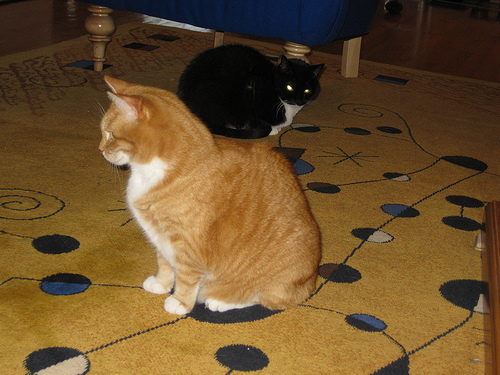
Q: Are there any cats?
A: Yes, there is a cat.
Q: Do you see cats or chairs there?
A: Yes, there is a cat.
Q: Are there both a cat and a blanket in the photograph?
A: No, there is a cat but no blankets.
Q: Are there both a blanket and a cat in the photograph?
A: No, there is a cat but no blankets.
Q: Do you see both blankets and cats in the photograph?
A: No, there is a cat but no blankets.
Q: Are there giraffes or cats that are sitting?
A: Yes, the cat is sitting.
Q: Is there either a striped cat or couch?
A: Yes, there is a striped cat.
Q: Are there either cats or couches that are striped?
A: Yes, the cat is striped.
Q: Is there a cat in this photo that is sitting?
A: Yes, there is a cat that is sitting.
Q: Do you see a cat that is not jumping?
A: Yes, there is a cat that is sitting .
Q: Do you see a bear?
A: No, there are no bears.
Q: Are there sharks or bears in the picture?
A: No, there are no bears or sharks.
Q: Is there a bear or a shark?
A: No, there are no bears or sharks.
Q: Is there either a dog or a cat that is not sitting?
A: No, there is a cat but it is sitting.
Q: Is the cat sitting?
A: Yes, the cat is sitting.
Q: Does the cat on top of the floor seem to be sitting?
A: Yes, the cat is sitting.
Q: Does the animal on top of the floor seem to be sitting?
A: Yes, the cat is sitting.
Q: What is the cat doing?
A: The cat is sitting.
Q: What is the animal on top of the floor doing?
A: The cat is sitting.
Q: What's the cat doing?
A: The cat is sitting.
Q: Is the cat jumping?
A: No, the cat is sitting.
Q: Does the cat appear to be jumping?
A: No, the cat is sitting.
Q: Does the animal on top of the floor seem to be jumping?
A: No, the cat is sitting.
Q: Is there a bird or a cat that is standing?
A: No, there is a cat but it is sitting.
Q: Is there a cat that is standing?
A: No, there is a cat but it is sitting.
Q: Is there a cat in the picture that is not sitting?
A: No, there is a cat but it is sitting.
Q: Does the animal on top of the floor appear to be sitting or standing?
A: The cat is sitting.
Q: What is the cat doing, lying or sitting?
A: The cat is sitting.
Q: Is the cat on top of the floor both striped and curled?
A: Yes, the cat is striped and curled.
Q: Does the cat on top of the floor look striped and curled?
A: Yes, the cat is striped and curled.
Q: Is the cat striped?
A: Yes, the cat is striped.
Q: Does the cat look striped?
A: Yes, the cat is striped.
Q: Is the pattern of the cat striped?
A: Yes, the cat is striped.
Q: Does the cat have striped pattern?
A: Yes, the cat is striped.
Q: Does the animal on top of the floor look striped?
A: Yes, the cat is striped.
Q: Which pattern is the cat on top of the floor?
A: The cat is striped.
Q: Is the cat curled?
A: Yes, the cat is curled.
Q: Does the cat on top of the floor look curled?
A: Yes, the cat is curled.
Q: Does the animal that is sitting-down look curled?
A: Yes, the cat is curled.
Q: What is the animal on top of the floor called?
A: The animal is a cat.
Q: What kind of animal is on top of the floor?
A: The animal is a cat.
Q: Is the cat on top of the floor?
A: Yes, the cat is on top of the floor.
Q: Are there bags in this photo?
A: No, there are no bags.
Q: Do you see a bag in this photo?
A: No, there are no bags.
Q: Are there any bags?
A: No, there are no bags.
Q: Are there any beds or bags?
A: No, there are no bags or beds.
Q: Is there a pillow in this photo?
A: No, there are no pillows.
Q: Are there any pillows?
A: No, there are no pillows.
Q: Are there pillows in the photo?
A: No, there are no pillows.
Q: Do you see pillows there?
A: No, there are no pillows.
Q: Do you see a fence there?
A: No, there are no fences.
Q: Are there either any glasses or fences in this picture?
A: No, there are no fences or glasses.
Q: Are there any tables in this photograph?
A: Yes, there is a table.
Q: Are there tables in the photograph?
A: Yes, there is a table.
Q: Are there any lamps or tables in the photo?
A: Yes, there is a table.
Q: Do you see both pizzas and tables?
A: No, there is a table but no pizzas.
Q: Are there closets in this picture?
A: No, there are no closets.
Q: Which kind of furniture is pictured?
A: The furniture is a table.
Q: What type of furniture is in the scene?
A: The furniture is a table.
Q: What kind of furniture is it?
A: The piece of furniture is a table.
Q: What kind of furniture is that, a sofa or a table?
A: That is a table.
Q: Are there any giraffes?
A: No, there are no giraffes.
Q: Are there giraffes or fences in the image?
A: No, there are no giraffes or fences.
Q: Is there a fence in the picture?
A: No, there are no fences.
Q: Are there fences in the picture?
A: No, there are no fences.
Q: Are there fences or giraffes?
A: No, there are no fences or giraffes.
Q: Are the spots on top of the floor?
A: Yes, the spots are on top of the floor.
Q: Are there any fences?
A: No, there are no fences.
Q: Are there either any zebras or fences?
A: No, there are no fences or zebras.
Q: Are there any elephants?
A: No, there are no elephants.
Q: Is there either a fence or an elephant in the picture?
A: No, there are no elephants or fences.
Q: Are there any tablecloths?
A: Yes, there is a tablecloth.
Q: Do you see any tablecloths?
A: Yes, there is a tablecloth.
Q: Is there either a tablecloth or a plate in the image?
A: Yes, there is a tablecloth.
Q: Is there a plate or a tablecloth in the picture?
A: Yes, there is a tablecloth.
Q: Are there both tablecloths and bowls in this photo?
A: No, there is a tablecloth but no bowls.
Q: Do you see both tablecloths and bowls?
A: No, there is a tablecloth but no bowls.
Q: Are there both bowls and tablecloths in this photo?
A: No, there is a tablecloth but no bowls.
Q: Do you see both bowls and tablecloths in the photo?
A: No, there is a tablecloth but no bowls.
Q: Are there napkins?
A: No, there are no napkins.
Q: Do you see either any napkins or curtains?
A: No, there are no napkins or curtains.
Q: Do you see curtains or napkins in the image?
A: No, there are no napkins or curtains.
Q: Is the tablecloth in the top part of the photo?
A: Yes, the tablecloth is in the top of the image.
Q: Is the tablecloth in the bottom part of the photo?
A: No, the tablecloth is in the top of the image.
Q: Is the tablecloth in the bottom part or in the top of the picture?
A: The tablecloth is in the top of the image.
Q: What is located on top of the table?
A: The tablecloth is on top of the table.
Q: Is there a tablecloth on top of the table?
A: Yes, there is a tablecloth on top of the table.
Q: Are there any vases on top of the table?
A: No, there is a tablecloth on top of the table.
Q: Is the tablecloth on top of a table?
A: Yes, the tablecloth is on top of a table.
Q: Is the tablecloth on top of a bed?
A: No, the tablecloth is on top of a table.